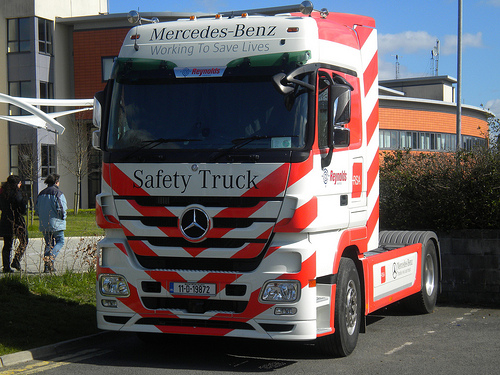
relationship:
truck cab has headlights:
[85, 2, 449, 355] [98, 274, 303, 318]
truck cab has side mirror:
[85, 2, 449, 355] [324, 73, 353, 156]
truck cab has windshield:
[85, 2, 449, 355] [108, 59, 312, 161]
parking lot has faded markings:
[5, 291, 497, 373] [375, 299, 484, 368]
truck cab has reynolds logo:
[85, 2, 449, 355] [323, 166, 353, 188]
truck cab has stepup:
[85, 2, 449, 355] [348, 214, 370, 248]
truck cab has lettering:
[85, 2, 449, 355] [145, 38, 279, 58]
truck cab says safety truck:
[85, 2, 449, 355] [126, 164, 270, 194]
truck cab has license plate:
[85, 2, 449, 355] [168, 277, 225, 303]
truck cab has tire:
[85, 2, 449, 355] [330, 254, 373, 373]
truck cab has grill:
[85, 2, 449, 355] [102, 194, 284, 334]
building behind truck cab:
[2, 2, 101, 217] [85, 2, 449, 355]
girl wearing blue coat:
[34, 169, 71, 271] [34, 183, 72, 235]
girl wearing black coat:
[1, 172, 32, 275] [3, 182, 30, 235]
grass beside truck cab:
[3, 272, 95, 347] [85, 2, 449, 355]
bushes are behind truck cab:
[385, 146, 498, 229] [85, 2, 449, 355]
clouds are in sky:
[381, 30, 483, 58] [358, 2, 494, 111]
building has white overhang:
[2, 2, 101, 217] [0, 86, 98, 140]